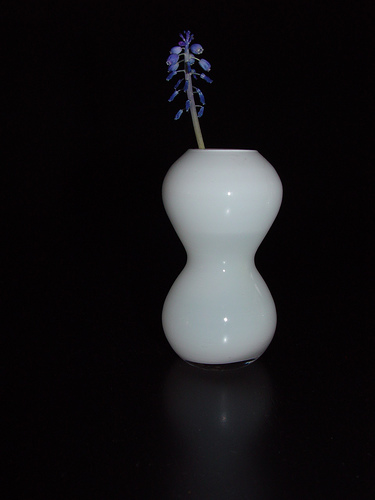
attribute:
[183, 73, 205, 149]
stem — thick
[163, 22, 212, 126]
flowers — blue 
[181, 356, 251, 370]
vase bottom — clear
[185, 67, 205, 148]
stem — long, thick